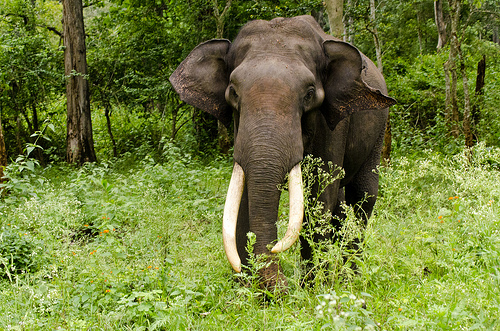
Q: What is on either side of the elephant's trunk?
A: Tusks.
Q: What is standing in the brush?
A: An elephant.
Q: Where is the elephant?
A: In the brush.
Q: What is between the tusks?
A: The elephant's trunk.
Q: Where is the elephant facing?
A: Forward.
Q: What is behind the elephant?
A: Trees.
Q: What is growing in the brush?
A: Small yellow flowers.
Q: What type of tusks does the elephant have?
A: Really long tusks.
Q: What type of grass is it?
A: Tall, green grass.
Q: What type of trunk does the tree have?
A: Brown.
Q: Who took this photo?
A: Jackson Mingus.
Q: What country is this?
A: South Africa.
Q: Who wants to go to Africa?
A: Jessie Wilkins.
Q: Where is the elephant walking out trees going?
A: Into grassy field.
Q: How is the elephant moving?
A: Walking.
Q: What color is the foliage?
A: Green.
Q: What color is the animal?
A: Gray.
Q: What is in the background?
A: Trees.